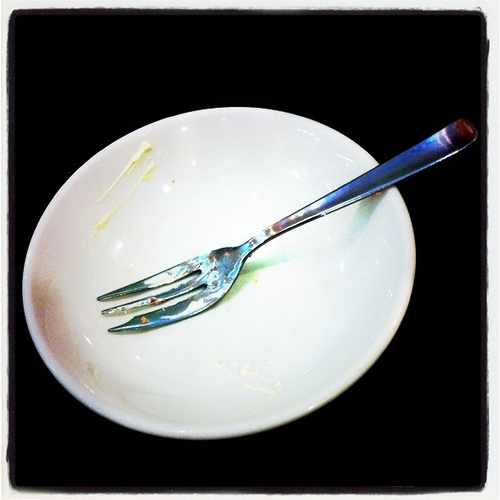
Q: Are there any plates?
A: Yes, there is a plate.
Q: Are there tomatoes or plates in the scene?
A: Yes, there is a plate.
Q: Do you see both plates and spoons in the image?
A: No, there is a plate but no spoons.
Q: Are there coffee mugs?
A: No, there are no coffee mugs.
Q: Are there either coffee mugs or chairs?
A: No, there are no coffee mugs or chairs.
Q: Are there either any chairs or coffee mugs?
A: No, there are no coffee mugs or chairs.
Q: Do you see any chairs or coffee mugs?
A: No, there are no coffee mugs or chairs.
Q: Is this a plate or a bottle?
A: This is a plate.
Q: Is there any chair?
A: No, there are no chairs.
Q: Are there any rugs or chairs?
A: No, there are no chairs or rugs.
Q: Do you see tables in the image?
A: Yes, there is a table.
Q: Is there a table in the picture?
A: Yes, there is a table.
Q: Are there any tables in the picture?
A: Yes, there is a table.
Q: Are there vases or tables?
A: Yes, there is a table.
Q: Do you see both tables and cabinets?
A: No, there is a table but no cabinets.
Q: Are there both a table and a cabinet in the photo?
A: No, there is a table but no cabinets.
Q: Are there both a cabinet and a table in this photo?
A: No, there is a table but no cabinets.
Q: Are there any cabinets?
A: No, there are no cabinets.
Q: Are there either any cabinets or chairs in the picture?
A: No, there are no cabinets or chairs.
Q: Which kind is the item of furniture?
A: The piece of furniture is a table.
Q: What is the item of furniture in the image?
A: The piece of furniture is a table.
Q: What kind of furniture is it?
A: The piece of furniture is a table.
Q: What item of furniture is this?
A: That is a table.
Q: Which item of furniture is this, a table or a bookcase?
A: That is a table.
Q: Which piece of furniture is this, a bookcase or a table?
A: That is a table.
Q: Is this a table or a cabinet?
A: This is a table.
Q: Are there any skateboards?
A: No, there are no skateboards.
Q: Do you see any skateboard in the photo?
A: No, there are no skateboards.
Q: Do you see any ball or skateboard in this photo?
A: No, there are no skateboards or balls.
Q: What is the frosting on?
A: The frosting is on the plate.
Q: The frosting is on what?
A: The frosting is on the plate.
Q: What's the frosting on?
A: The frosting is on the plate.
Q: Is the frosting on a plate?
A: Yes, the frosting is on a plate.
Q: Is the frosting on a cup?
A: No, the frosting is on a plate.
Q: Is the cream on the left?
A: Yes, the cream is on the left of the image.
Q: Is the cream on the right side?
A: No, the cream is on the left of the image.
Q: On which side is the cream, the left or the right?
A: The cream is on the left of the image.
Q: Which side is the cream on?
A: The cream is on the left of the image.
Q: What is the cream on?
A: The cream is on the plate.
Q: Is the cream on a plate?
A: Yes, the cream is on a plate.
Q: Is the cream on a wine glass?
A: No, the cream is on a plate.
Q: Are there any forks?
A: Yes, there is a fork.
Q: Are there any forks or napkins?
A: Yes, there is a fork.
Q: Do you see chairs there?
A: No, there are no chairs.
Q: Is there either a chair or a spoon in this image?
A: No, there are no chairs or spoons.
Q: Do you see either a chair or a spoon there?
A: No, there are no chairs or spoons.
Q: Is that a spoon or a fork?
A: That is a fork.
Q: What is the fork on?
A: The fork is on the plate.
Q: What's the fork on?
A: The fork is on the plate.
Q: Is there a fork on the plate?
A: Yes, there is a fork on the plate.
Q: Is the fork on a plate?
A: Yes, the fork is on a plate.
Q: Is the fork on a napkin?
A: No, the fork is on a plate.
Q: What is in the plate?
A: The fork is in the plate.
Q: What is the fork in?
A: The fork is in the plate.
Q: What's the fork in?
A: The fork is in the plate.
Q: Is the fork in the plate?
A: Yes, the fork is in the plate.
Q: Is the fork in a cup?
A: No, the fork is in the plate.